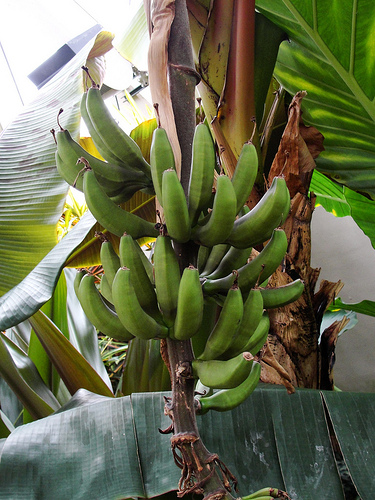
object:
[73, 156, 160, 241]
banana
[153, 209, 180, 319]
bananas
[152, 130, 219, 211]
olive colored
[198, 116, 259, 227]
banana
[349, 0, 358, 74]
vein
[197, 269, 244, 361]
banana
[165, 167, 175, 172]
nub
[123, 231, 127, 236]
nub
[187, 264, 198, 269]
nub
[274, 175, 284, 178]
nub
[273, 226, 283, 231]
nub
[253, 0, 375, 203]
banana leaf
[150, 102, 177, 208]
banana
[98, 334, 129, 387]
grass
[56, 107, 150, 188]
banana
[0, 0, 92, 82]
sun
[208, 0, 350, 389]
trunk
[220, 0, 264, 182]
stick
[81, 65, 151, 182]
banana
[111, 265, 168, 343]
banana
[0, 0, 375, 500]
tree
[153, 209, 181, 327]
banana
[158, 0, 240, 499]
brown stick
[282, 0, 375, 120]
spine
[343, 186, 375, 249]
leaf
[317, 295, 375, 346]
leaf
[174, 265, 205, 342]
banana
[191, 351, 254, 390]
banana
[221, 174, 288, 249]
banana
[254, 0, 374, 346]
plant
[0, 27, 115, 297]
leaf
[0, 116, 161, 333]
leaf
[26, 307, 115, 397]
leaf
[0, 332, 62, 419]
leaf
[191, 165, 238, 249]
banana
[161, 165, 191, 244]
banana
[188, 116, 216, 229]
banana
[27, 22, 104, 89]
purple box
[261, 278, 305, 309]
bananas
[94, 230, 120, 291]
banana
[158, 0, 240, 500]
trunk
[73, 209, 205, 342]
upwards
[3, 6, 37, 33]
sky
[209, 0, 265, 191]
spine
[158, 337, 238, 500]
stem